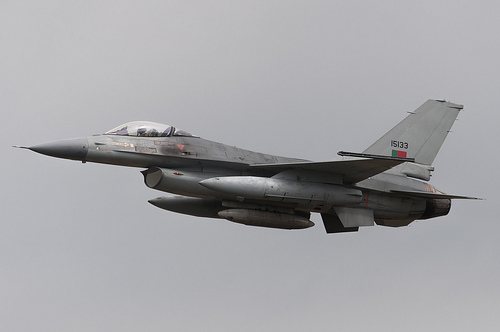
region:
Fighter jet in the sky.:
[14, 56, 486, 261]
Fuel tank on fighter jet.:
[144, 163, 373, 224]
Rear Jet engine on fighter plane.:
[416, 165, 474, 263]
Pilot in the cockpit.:
[79, 103, 171, 150]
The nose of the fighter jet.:
[31, 128, 150, 220]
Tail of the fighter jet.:
[329, 103, 484, 172]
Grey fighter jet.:
[61, 65, 495, 248]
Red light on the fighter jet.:
[170, 164, 190, 184]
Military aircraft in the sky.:
[29, 57, 472, 276]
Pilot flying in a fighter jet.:
[14, 74, 337, 324]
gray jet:
[9, 133, 449, 255]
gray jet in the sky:
[0, 119, 495, 248]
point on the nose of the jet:
[4, 138, 158, 168]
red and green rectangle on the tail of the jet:
[381, 143, 440, 173]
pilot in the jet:
[98, 127, 190, 151]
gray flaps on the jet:
[315, 203, 399, 233]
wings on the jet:
[260, 150, 449, 199]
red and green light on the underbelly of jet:
[168, 171, 200, 183]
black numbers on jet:
[389, 137, 431, 157]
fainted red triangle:
[163, 136, 218, 161]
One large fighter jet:
[9, 66, 493, 265]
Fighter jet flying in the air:
[7, 13, 498, 280]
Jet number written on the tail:
[373, 130, 420, 161]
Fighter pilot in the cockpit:
[127, 117, 159, 137]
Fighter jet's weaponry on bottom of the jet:
[125, 167, 366, 236]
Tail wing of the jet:
[365, 67, 474, 181]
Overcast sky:
[23, 15, 402, 141]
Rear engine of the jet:
[423, 177, 463, 227]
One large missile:
[194, 168, 372, 210]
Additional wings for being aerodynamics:
[314, 202, 380, 240]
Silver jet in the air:
[37, 108, 414, 261]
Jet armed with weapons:
[199, 178, 361, 250]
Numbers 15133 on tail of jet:
[384, 127, 429, 164]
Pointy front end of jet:
[11, 137, 86, 172]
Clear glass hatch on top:
[98, 112, 190, 150]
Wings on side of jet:
[256, 117, 489, 235]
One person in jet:
[118, 112, 175, 155]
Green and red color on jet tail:
[370, 88, 457, 193]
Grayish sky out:
[92, 48, 407, 104]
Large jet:
[40, 120, 437, 210]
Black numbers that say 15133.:
[379, 129, 426, 152]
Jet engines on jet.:
[141, 171, 373, 233]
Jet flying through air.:
[43, 120, 448, 229]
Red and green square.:
[379, 148, 413, 161]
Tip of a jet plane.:
[5, 107, 87, 188]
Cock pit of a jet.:
[94, 112, 221, 150]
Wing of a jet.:
[220, 142, 402, 194]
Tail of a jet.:
[335, 86, 473, 188]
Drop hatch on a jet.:
[292, 198, 385, 254]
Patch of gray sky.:
[6, 217, 126, 327]